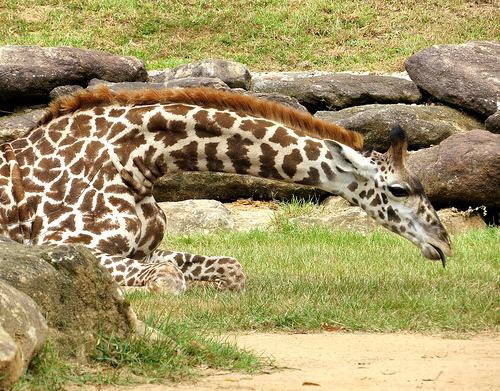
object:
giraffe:
[0, 84, 453, 297]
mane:
[32, 83, 371, 146]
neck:
[126, 83, 356, 199]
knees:
[138, 252, 245, 302]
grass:
[251, 247, 414, 325]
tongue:
[426, 245, 454, 268]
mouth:
[410, 214, 476, 271]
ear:
[320, 131, 375, 184]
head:
[347, 123, 454, 274]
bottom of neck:
[116, 158, 186, 210]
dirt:
[244, 324, 439, 390]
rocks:
[1, 232, 100, 351]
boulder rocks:
[338, 43, 499, 177]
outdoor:
[3, 2, 494, 391]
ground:
[257, 274, 499, 379]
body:
[1, 140, 158, 254]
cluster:
[370, 65, 492, 158]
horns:
[380, 117, 417, 170]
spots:
[144, 113, 190, 150]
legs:
[29, 224, 244, 299]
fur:
[53, 128, 139, 196]